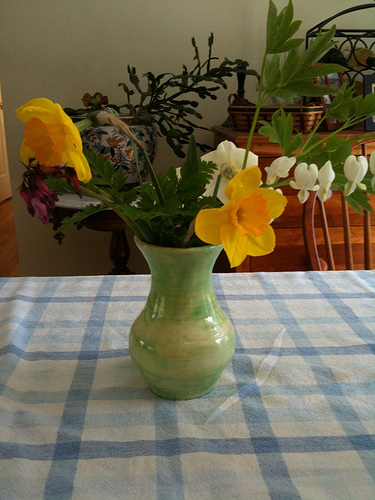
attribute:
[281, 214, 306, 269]
cabinet — Wooden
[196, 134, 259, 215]
flower — small, white